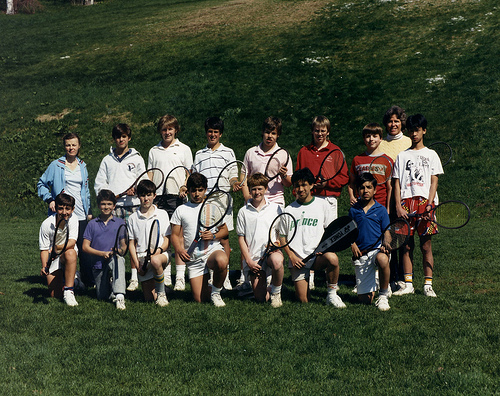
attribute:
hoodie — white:
[94, 147, 144, 193]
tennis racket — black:
[248, 212, 298, 280]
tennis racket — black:
[184, 189, 235, 263]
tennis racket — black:
[48, 211, 68, 272]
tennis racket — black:
[315, 147, 347, 184]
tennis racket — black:
[264, 142, 289, 179]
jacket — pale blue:
[36, 156, 91, 218]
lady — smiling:
[358, 85, 422, 173]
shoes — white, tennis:
[320, 286, 347, 311]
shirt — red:
[383, 133, 437, 212]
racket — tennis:
[236, 205, 327, 258]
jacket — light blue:
[34, 152, 92, 217]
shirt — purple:
[87, 215, 129, 248]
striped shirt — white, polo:
[192, 146, 238, 191]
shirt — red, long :
[293, 141, 348, 189]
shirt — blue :
[345, 199, 393, 254]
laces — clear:
[209, 206, 219, 216]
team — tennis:
[35, 100, 446, 314]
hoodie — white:
[91, 143, 149, 203]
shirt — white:
[35, 205, 78, 256]